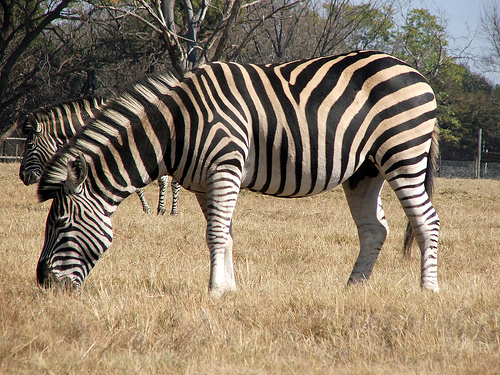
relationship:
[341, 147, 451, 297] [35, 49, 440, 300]
back legs of zebra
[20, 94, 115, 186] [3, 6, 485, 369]
animal in pasture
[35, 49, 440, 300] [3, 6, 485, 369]
zebra in pasture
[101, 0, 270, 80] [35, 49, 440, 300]
tree behind zebra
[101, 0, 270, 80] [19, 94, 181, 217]
tree behind animal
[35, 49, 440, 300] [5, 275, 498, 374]
zebra eating grass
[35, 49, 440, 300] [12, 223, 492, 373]
zebra eating grass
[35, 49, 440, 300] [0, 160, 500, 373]
zebra standing field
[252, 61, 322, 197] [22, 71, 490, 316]
stripe on zebra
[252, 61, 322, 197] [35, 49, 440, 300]
stripe on zebra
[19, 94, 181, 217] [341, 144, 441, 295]
animal has back legs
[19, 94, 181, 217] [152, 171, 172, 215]
animal has legs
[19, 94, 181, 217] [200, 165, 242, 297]
animal has legs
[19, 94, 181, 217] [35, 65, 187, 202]
animal has mane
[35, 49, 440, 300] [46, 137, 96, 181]
zebra has ear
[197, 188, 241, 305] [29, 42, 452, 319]
legs of zebra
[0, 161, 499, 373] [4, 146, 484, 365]
grass in field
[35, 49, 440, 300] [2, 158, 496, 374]
zebra grazing in pasture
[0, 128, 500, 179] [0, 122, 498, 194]
fence in distance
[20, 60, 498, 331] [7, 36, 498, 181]
zebra in background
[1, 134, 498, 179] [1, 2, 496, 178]
fence in background